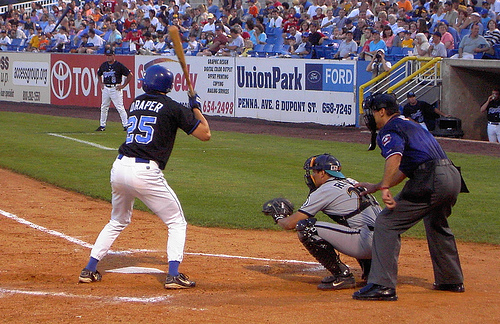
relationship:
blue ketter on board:
[230, 62, 248, 101] [233, 55, 358, 126]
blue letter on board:
[250, 65, 260, 87] [234, 56, 358, 126]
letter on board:
[292, 65, 304, 89] [233, 55, 358, 126]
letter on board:
[279, 72, 288, 87] [233, 55, 358, 126]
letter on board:
[292, 65, 304, 89] [277, 31, 368, 135]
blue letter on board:
[238, 97, 357, 118] [234, 56, 358, 126]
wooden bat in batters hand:
[166, 23, 196, 97] [185, 90, 202, 110]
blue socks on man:
[165, 255, 181, 280] [79, 63, 212, 287]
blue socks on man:
[82, 252, 100, 277] [79, 63, 212, 287]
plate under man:
[102, 259, 169, 282] [79, 63, 212, 287]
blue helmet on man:
[140, 62, 175, 97] [79, 63, 212, 287]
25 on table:
[121, 114, 157, 147] [95, 115, 165, 146]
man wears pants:
[79, 63, 212, 289] [89, 152, 187, 262]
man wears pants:
[96, 47, 133, 133] [99, 83, 129, 125]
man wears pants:
[481, 86, 499, 142] [487, 122, 499, 142]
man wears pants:
[402, 90, 453, 134] [418, 122, 429, 132]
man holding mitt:
[256, 144, 402, 295] [256, 188, 293, 228]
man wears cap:
[96, 47, 133, 133] [101, 47, 113, 54]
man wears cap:
[402, 90, 448, 135] [407, 90, 414, 97]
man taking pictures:
[363, 48, 390, 81] [2, 1, 499, 322]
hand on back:
[344, 179, 374, 199] [324, 176, 385, 262]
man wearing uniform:
[260, 152, 382, 295] [296, 175, 385, 259]